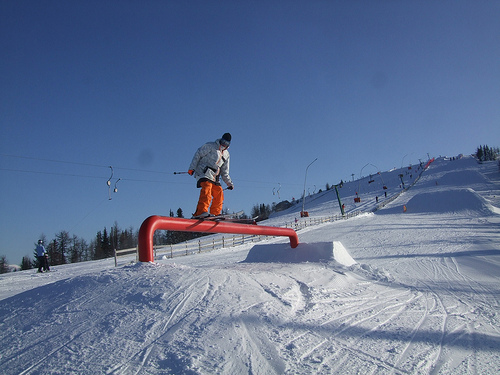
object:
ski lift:
[99, 156, 129, 202]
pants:
[193, 180, 225, 215]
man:
[187, 132, 235, 225]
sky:
[2, 0, 129, 114]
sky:
[327, 0, 494, 65]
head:
[219, 132, 232, 147]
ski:
[194, 211, 227, 221]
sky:
[163, 57, 322, 119]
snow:
[399, 272, 497, 370]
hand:
[187, 168, 194, 177]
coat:
[189, 141, 234, 187]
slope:
[0, 261, 499, 371]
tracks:
[0, 295, 148, 372]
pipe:
[138, 216, 298, 263]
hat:
[222, 132, 233, 142]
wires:
[0, 151, 329, 196]